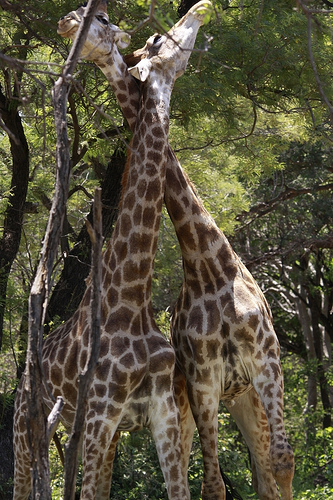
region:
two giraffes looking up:
[59, 6, 218, 282]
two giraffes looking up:
[55, 10, 235, 156]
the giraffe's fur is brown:
[111, 281, 189, 458]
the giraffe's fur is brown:
[189, 278, 278, 389]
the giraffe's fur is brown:
[112, 207, 182, 344]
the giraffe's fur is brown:
[164, 218, 251, 387]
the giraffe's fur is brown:
[101, 233, 173, 426]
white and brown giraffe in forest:
[9, 0, 257, 499]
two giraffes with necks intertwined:
[7, 0, 328, 496]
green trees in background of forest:
[1, 0, 331, 495]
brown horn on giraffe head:
[121, 46, 150, 67]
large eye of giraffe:
[144, 29, 167, 50]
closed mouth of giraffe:
[54, 11, 79, 43]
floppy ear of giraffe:
[109, 27, 133, 51]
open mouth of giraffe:
[179, 3, 218, 26]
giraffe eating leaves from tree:
[13, 0, 214, 499]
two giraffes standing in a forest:
[25, 22, 311, 491]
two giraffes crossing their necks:
[58, 5, 258, 313]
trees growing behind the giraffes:
[241, 204, 332, 407]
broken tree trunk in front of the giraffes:
[37, 156, 115, 495]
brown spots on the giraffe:
[109, 279, 166, 377]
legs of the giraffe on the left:
[4, 391, 188, 488]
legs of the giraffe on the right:
[175, 367, 311, 494]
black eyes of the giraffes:
[83, 8, 177, 49]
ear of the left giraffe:
[124, 53, 159, 86]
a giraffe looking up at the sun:
[135, 0, 224, 97]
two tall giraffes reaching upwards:
[14, 0, 304, 491]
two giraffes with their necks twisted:
[47, 0, 241, 311]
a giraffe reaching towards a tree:
[117, 1, 214, 136]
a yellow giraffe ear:
[127, 51, 156, 87]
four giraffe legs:
[170, 356, 302, 498]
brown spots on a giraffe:
[76, 296, 146, 381]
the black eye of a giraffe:
[148, 28, 165, 55]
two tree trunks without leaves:
[22, 3, 106, 498]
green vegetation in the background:
[1, 15, 331, 491]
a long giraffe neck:
[87, 79, 176, 324]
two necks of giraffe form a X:
[41, 1, 252, 229]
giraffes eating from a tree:
[0, 4, 331, 240]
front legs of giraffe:
[68, 386, 186, 498]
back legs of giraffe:
[10, 401, 57, 498]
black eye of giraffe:
[147, 26, 168, 47]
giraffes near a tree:
[8, 0, 303, 494]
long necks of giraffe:
[103, 83, 228, 287]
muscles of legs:
[176, 271, 288, 432]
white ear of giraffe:
[118, 55, 160, 85]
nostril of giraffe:
[48, 10, 78, 32]